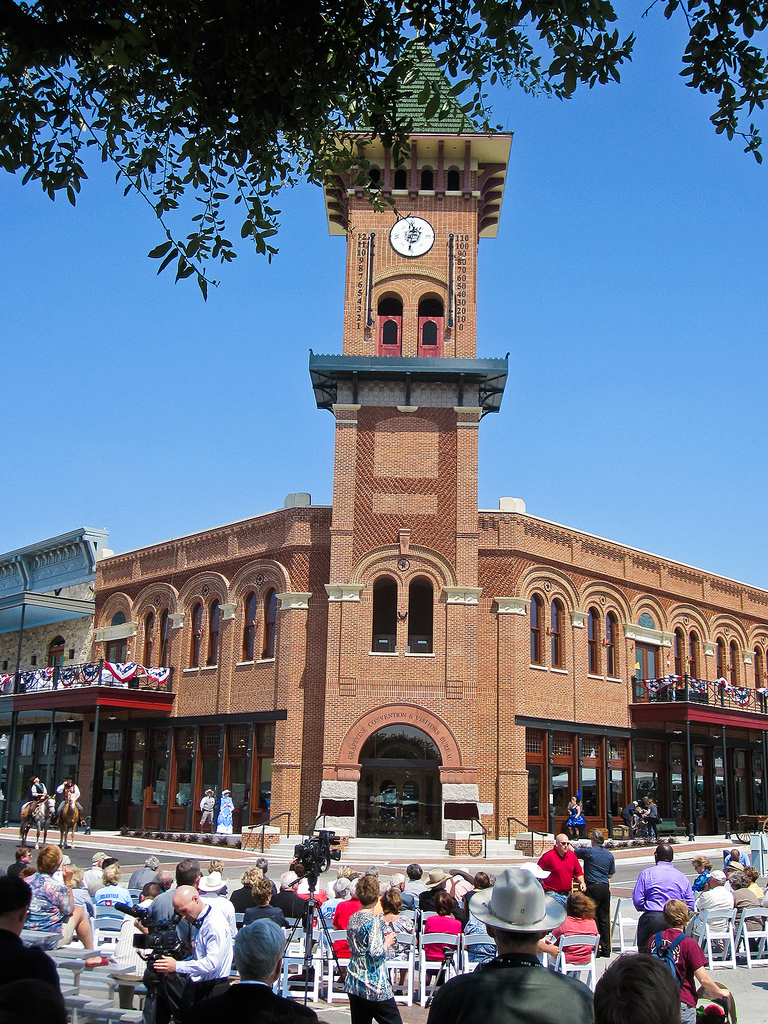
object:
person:
[423, 889, 463, 1006]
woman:
[18, 844, 110, 968]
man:
[632, 843, 695, 953]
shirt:
[632, 860, 695, 914]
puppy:
[405, 871, 487, 945]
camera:
[287, 829, 343, 892]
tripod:
[274, 889, 335, 1007]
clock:
[389, 216, 435, 257]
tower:
[305, 32, 516, 512]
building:
[82, 492, 766, 837]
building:
[371, 573, 398, 652]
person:
[26, 775, 47, 829]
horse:
[19, 792, 58, 847]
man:
[425, 868, 596, 1022]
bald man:
[536, 833, 587, 894]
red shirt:
[536, 844, 584, 891]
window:
[263, 588, 277, 660]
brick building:
[0, 39, 768, 860]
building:
[0, 496, 764, 835]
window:
[531, 591, 542, 660]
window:
[551, 600, 566, 666]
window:
[588, 608, 597, 674]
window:
[606, 611, 620, 677]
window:
[526, 762, 541, 816]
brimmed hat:
[469, 870, 568, 938]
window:
[531, 592, 568, 668]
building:
[69, 28, 768, 844]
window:
[588, 607, 597, 675]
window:
[190, 594, 202, 670]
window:
[241, 586, 258, 663]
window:
[638, 613, 657, 630]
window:
[587, 607, 617, 679]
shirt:
[424, 914, 462, 961]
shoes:
[77, 945, 120, 981]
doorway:
[356, 723, 443, 841]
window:
[371, 573, 397, 653]